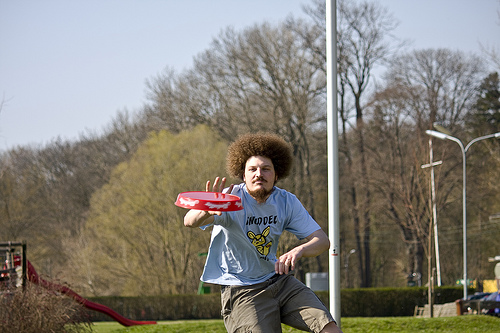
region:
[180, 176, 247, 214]
red Frisbee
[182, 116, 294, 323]
boy with Frisbee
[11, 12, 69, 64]
white clouds in blue sky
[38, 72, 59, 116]
white clouds in blue sky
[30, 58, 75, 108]
white clouds in blue sky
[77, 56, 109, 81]
white clouds in blue sky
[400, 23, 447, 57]
white clouds in blue sky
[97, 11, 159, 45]
white clouds in blue sky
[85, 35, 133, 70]
white clouds in blue sky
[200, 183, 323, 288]
Blue t shirt with a yellow cartoon character on it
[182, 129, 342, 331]
Man reaching to catch a frisbee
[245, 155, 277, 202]
Man's face with a mustache and goatee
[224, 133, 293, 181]
Brownish red afro hairstyle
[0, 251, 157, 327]
Long red wavy children's slide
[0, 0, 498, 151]
Light blue cloudless sky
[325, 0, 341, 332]
Silver light pole with a sticker on it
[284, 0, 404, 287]
Tall tree with no leaves on the branches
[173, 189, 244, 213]
Red frisbee with white shapes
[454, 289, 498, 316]
Group of parked cars in the disstance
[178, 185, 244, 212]
Frisbee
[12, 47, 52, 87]
white clouds in blue sky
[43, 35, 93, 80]
white clouds in blue sky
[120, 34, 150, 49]
white clouds in blue sky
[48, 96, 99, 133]
white clouds in blue sky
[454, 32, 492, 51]
white clouds in blue sky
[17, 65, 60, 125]
white clouds in blue sky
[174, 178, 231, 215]
red frisbee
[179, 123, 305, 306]
boy with frisbee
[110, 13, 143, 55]
white clouds in blue sky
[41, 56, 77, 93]
white clouds in blue sky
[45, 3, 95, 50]
white clouds in blue sky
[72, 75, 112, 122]
white clouds in blue sky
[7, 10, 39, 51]
white clouds in blue sky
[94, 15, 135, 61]
white clouds in blue sky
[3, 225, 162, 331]
red child's slide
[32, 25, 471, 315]
photograph taken at a park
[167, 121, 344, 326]
man about to catch frisbe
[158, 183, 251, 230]
red frisbee with white design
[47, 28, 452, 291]
trees with no leaves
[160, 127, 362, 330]
man reaching for frisbee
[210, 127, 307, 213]
man with a beard on his face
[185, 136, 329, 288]
man wearing blue t-shirt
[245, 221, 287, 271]
yellow character on blue t-shirt